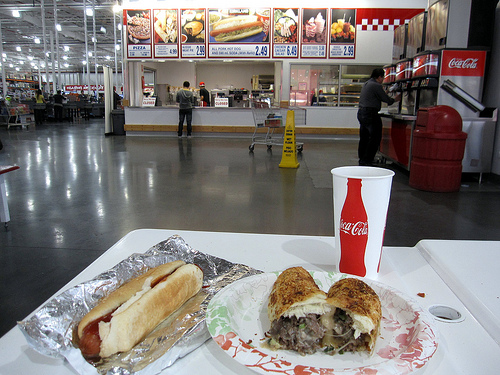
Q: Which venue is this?
A: This is a store.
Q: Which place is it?
A: It is a store.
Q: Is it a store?
A: Yes, it is a store.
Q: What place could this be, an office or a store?
A: It is a store.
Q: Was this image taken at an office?
A: No, the picture was taken in a store.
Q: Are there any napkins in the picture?
A: No, there are no napkins.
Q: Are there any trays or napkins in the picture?
A: No, there are no napkins or trays.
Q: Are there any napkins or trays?
A: No, there are no napkins or trays.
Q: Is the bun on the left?
A: Yes, the bun is on the left of the image.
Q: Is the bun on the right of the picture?
A: No, the bun is on the left of the image.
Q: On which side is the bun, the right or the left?
A: The bun is on the left of the image.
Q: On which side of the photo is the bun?
A: The bun is on the left of the image.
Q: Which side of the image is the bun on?
A: The bun is on the left of the image.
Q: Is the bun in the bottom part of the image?
A: Yes, the bun is in the bottom of the image.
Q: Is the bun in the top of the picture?
A: No, the bun is in the bottom of the image.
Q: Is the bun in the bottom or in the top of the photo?
A: The bun is in the bottom of the image.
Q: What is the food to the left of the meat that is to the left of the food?
A: The food is a bun.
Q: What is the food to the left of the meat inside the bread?
A: The food is a bun.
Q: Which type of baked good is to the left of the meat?
A: The food is a bun.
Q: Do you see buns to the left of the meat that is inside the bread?
A: Yes, there is a bun to the left of the meat.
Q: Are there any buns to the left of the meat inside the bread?
A: Yes, there is a bun to the left of the meat.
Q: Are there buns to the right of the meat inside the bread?
A: No, the bun is to the left of the meat.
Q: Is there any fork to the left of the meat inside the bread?
A: No, there is a bun to the left of the meat.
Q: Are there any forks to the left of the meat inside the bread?
A: No, there is a bun to the left of the meat.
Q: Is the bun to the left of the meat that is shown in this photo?
A: Yes, the bun is to the left of the meat.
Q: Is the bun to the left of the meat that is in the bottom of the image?
A: Yes, the bun is to the left of the meat.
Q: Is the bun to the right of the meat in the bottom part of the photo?
A: No, the bun is to the left of the meat.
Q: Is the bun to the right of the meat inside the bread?
A: No, the bun is to the left of the meat.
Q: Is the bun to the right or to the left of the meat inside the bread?
A: The bun is to the left of the meat.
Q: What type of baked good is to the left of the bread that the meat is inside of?
A: The food is a bun.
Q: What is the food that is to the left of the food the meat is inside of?
A: The food is a bun.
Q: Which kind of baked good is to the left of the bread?
A: The food is a bun.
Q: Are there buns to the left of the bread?
A: Yes, there is a bun to the left of the bread.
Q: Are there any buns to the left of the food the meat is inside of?
A: Yes, there is a bun to the left of the bread.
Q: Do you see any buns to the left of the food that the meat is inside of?
A: Yes, there is a bun to the left of the bread.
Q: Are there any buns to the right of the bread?
A: No, the bun is to the left of the bread.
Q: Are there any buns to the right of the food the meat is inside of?
A: No, the bun is to the left of the bread.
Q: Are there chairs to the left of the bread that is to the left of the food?
A: No, there is a bun to the left of the bread.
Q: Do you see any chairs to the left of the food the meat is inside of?
A: No, there is a bun to the left of the bread.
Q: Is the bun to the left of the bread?
A: Yes, the bun is to the left of the bread.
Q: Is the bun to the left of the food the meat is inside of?
A: Yes, the bun is to the left of the bread.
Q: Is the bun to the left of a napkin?
A: No, the bun is to the left of the bread.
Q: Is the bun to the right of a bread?
A: No, the bun is to the left of a bread.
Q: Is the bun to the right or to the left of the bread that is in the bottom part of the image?
A: The bun is to the left of the bread.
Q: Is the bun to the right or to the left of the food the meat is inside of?
A: The bun is to the left of the bread.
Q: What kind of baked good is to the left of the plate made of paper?
A: The food is a bun.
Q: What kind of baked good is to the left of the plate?
A: The food is a bun.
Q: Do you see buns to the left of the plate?
A: Yes, there is a bun to the left of the plate.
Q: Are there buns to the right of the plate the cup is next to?
A: No, the bun is to the left of the plate.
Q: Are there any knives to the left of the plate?
A: No, there is a bun to the left of the plate.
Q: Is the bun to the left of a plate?
A: Yes, the bun is to the left of a plate.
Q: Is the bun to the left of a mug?
A: No, the bun is to the left of a plate.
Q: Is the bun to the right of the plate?
A: No, the bun is to the left of the plate.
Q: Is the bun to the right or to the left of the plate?
A: The bun is to the left of the plate.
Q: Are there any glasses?
A: No, there are no glasses.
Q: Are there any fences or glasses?
A: No, there are no glasses or fences.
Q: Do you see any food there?
A: Yes, there is food.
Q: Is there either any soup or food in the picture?
A: Yes, there is food.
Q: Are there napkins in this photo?
A: No, there are no napkins.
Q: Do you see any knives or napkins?
A: No, there are no napkins or knives.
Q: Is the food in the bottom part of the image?
A: Yes, the food is in the bottom of the image.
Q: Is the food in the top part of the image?
A: No, the food is in the bottom of the image.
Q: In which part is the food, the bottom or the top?
A: The food is in the bottom of the image.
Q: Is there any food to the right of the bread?
A: Yes, there is food to the right of the bread.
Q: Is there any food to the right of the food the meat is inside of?
A: Yes, there is food to the right of the bread.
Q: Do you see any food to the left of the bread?
A: No, the food is to the right of the bread.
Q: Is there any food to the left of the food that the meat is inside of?
A: No, the food is to the right of the bread.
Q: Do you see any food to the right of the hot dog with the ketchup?
A: Yes, there is food to the right of the hot dog.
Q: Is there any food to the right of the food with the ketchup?
A: Yes, there is food to the right of the hot dog.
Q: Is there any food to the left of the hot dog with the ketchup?
A: No, the food is to the right of the hot dog.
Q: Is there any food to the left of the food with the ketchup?
A: No, the food is to the right of the hot dog.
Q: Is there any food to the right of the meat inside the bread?
A: Yes, there is food to the right of the meat.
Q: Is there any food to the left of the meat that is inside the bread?
A: No, the food is to the right of the meat.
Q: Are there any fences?
A: No, there are no fences.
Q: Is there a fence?
A: No, there are no fences.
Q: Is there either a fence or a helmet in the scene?
A: No, there are no fences or helmets.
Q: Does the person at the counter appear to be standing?
A: Yes, the person is standing.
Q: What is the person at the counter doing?
A: The person is standing.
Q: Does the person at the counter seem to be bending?
A: No, the person is standing.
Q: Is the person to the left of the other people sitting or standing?
A: The person is standing.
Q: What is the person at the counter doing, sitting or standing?
A: The person is standing.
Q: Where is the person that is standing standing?
A: The person is standing at the counter.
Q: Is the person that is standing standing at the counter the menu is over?
A: Yes, the person is standing at the counter.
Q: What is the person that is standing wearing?
A: The person is wearing a shirt.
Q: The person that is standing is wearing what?
A: The person is wearing a shirt.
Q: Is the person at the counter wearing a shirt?
A: Yes, the person is wearing a shirt.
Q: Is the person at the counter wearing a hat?
A: No, the person is wearing a shirt.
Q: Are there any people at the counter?
A: Yes, there is a person at the counter.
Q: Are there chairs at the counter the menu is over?
A: No, there is a person at the counter.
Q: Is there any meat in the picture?
A: Yes, there is meat.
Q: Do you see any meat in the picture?
A: Yes, there is meat.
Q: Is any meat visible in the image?
A: Yes, there is meat.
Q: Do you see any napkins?
A: No, there are no napkins.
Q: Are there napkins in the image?
A: No, there are no napkins.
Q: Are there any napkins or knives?
A: No, there are no napkins or knives.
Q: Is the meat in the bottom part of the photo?
A: Yes, the meat is in the bottom of the image.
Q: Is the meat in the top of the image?
A: No, the meat is in the bottom of the image.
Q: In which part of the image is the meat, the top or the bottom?
A: The meat is in the bottom of the image.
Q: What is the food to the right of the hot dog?
A: The food is meat.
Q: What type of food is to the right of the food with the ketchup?
A: The food is meat.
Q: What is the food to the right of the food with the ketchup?
A: The food is meat.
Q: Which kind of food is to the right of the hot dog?
A: The food is meat.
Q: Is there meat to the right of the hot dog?
A: Yes, there is meat to the right of the hot dog.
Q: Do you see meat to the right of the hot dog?
A: Yes, there is meat to the right of the hot dog.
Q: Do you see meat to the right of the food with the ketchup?
A: Yes, there is meat to the right of the hot dog.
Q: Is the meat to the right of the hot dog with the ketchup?
A: Yes, the meat is to the right of the hot dog.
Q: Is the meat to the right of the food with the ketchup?
A: Yes, the meat is to the right of the hot dog.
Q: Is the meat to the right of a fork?
A: No, the meat is to the right of the hot dog.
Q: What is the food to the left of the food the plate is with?
A: The food is meat.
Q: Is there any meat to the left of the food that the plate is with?
A: Yes, there is meat to the left of the food.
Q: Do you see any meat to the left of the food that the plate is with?
A: Yes, there is meat to the left of the food.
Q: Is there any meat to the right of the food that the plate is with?
A: No, the meat is to the left of the food.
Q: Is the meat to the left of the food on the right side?
A: Yes, the meat is to the left of the food.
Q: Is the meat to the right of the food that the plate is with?
A: No, the meat is to the left of the food.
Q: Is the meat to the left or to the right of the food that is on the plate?
A: The meat is to the left of the food.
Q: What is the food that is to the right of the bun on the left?
A: The food is meat.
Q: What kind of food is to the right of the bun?
A: The food is meat.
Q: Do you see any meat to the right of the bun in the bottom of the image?
A: Yes, there is meat to the right of the bun.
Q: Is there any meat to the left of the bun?
A: No, the meat is to the right of the bun.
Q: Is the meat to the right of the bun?
A: Yes, the meat is to the right of the bun.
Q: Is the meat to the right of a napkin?
A: No, the meat is to the right of the bun.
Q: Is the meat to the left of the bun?
A: No, the meat is to the right of the bun.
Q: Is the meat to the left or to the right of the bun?
A: The meat is to the right of the bun.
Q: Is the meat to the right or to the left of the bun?
A: The meat is to the right of the bun.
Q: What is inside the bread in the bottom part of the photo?
A: The meat is inside the bread.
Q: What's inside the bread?
A: The meat is inside the bread.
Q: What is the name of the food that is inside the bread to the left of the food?
A: The food is meat.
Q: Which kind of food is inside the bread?
A: The food is meat.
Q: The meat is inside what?
A: The meat is inside the bread.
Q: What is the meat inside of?
A: The meat is inside the bread.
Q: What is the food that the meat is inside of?
A: The food is a bread.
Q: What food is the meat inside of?
A: The meat is inside the bread.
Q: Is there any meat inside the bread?
A: Yes, there is meat inside the bread.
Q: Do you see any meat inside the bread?
A: Yes, there is meat inside the bread.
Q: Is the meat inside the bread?
A: Yes, the meat is inside the bread.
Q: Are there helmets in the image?
A: No, there are no helmets.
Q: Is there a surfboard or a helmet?
A: No, there are no helmets or surfboards.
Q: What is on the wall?
A: The menu is on the wall.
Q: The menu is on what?
A: The menu is on the wall.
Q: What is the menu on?
A: The menu is on the wall.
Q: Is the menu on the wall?
A: Yes, the menu is on the wall.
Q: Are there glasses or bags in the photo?
A: No, there are no glasses or bags.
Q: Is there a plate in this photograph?
A: Yes, there is a plate.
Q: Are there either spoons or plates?
A: Yes, there is a plate.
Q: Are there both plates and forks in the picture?
A: No, there is a plate but no forks.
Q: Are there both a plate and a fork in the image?
A: No, there is a plate but no forks.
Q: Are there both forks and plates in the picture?
A: No, there is a plate but no forks.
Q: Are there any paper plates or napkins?
A: Yes, there is a paper plate.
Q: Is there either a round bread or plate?
A: Yes, there is a round plate.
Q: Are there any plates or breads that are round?
A: Yes, the plate is round.